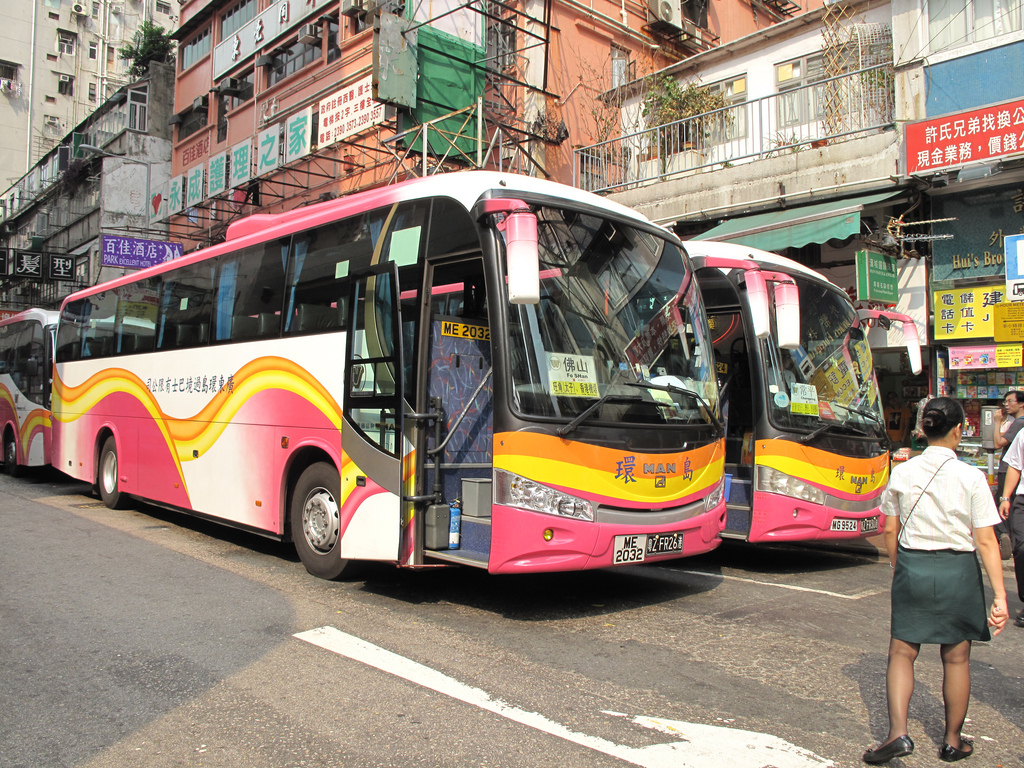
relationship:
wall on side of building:
[596, 5, 922, 179] [128, 9, 984, 280]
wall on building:
[165, 0, 540, 239] [167, 5, 792, 228]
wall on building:
[591, 0, 922, 228] [567, 1, 1011, 352]